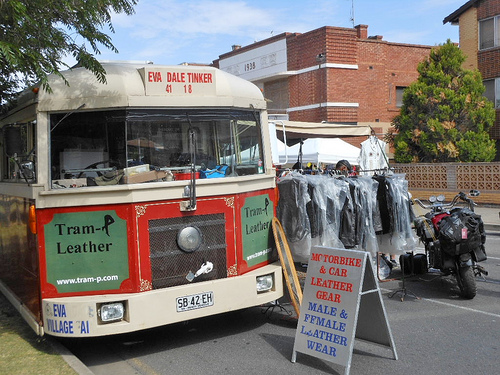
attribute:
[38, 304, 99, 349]
print — blue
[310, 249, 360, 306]
print — red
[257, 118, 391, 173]
vendor tents — up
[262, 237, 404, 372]
sign — advertising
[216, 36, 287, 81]
white sign — square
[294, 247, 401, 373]
sign — gray, advertising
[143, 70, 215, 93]
text — red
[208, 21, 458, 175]
building — brick, red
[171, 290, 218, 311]
license plate — white, black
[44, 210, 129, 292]
sign — large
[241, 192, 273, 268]
sign — large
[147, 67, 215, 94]
sign — large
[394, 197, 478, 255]
motorcycle — antique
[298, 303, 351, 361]
sign — gray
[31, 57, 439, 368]
store — portable, leather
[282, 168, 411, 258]
bags — plastic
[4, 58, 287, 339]
bus — old, red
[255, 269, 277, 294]
light — square, white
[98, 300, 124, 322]
light — white, square